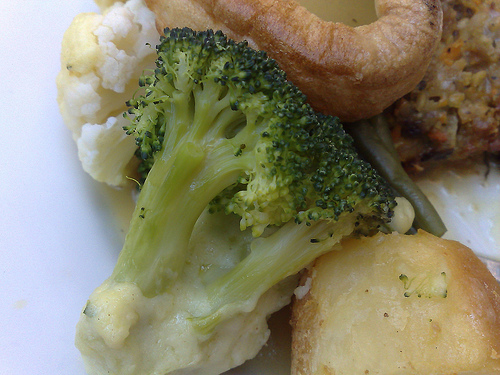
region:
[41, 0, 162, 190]
Cauliflower head on a plate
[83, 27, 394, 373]
Broccoli on a plate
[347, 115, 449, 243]
Green bean on a plate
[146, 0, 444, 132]
Bread on a plate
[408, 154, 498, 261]
White sauce on a plate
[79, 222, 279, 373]
White sauce covering broccoli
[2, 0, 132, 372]
White plate with vegetables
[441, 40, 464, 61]
Carrot bit in a hash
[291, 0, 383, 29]
Curve in a roll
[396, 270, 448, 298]
Broccoli pieces on bread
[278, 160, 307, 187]
green speckle on broccoli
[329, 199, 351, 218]
green speckle on broccoli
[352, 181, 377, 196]
green speckle on broccoli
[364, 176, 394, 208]
green speckle on broccoli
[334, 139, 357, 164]
green speckle on broccoli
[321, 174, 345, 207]
green speckle on broccoli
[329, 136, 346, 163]
green speckle on broccoli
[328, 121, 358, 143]
green speckle on broccoli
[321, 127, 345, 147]
green speckle on broccoli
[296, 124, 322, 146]
green speckle on broccoli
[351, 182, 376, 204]
part fo a vege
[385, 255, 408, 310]
part f a food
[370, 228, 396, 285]
edge of a food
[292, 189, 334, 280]
edge of a vege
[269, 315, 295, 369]
part of a shade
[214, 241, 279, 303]
part of a stalk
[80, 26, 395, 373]
a piece of broccoli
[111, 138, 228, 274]
light green stem of the broccoli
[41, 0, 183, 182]
hunk of white cauliflower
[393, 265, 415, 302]
green speck on the food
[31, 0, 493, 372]
food on a plate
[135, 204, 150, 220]
dark green spot on the broccoli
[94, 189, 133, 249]
shadow on the plate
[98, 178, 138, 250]
shadow from the food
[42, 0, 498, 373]
a pile of food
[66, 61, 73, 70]
green speck on the cauliflower